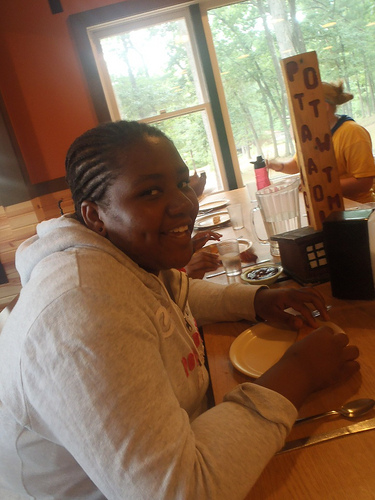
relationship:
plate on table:
[231, 321, 302, 376] [291, 449, 373, 499]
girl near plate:
[49, 116, 228, 375] [231, 321, 302, 376]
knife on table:
[275, 416, 375, 454] [291, 449, 373, 499]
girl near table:
[49, 116, 228, 375] [291, 449, 373, 499]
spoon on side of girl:
[295, 396, 367, 426] [0, 120, 299, 498]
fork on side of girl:
[303, 429, 367, 446] [0, 120, 299, 498]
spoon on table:
[293, 400, 368, 421] [295, 369, 370, 477]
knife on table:
[293, 423, 368, 446] [295, 369, 370, 477]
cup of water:
[216, 237, 243, 276] [224, 254, 241, 275]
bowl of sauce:
[243, 264, 279, 282] [248, 269, 277, 274]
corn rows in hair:
[64, 124, 164, 195] [57, 120, 161, 198]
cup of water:
[218, 244, 243, 277] [220, 254, 241, 274]